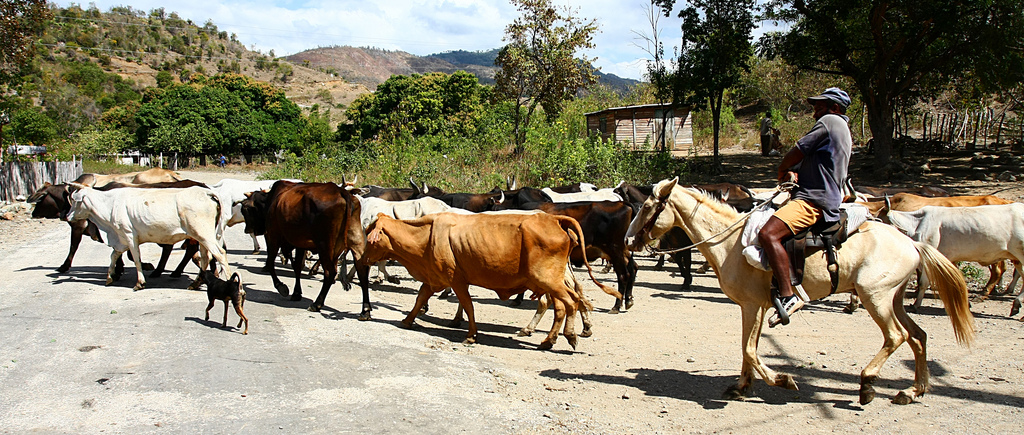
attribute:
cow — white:
[68, 169, 308, 310]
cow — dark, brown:
[254, 158, 378, 295]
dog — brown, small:
[167, 262, 302, 347]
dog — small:
[176, 253, 252, 346]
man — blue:
[763, 80, 856, 322]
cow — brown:
[234, 179, 366, 305]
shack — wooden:
[590, 95, 701, 156]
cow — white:
[57, 183, 241, 287]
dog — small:
[187, 263, 257, 333]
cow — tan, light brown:
[357, 207, 597, 350]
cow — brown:
[240, 175, 362, 301]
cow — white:
[53, 184, 239, 280]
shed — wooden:
[584, 91, 699, 169]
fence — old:
[895, 114, 1017, 145]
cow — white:
[878, 199, 1023, 312]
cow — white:
[63, 181, 236, 292]